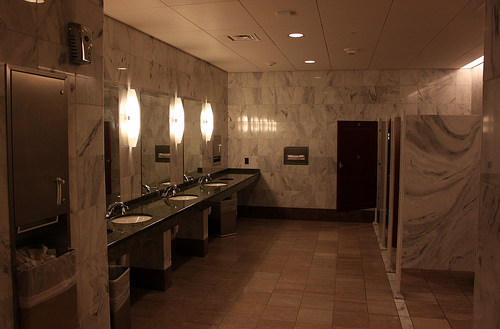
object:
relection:
[229, 108, 285, 138]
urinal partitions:
[367, 107, 480, 295]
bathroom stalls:
[404, 110, 497, 296]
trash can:
[217, 198, 238, 235]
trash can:
[105, 261, 134, 327]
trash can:
[15, 242, 80, 327]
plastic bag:
[212, 199, 235, 237]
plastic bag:
[110, 263, 132, 308]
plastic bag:
[10, 248, 77, 327]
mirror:
[102, 88, 121, 204]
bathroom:
[7, 2, 495, 324]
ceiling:
[126, 1, 481, 65]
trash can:
[4, 236, 97, 327]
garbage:
[3, 229, 80, 266]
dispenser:
[283, 145, 309, 165]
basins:
[109, 214, 157, 223]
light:
[236, 116, 276, 133]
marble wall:
[226, 67, 471, 206]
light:
[199, 101, 213, 141]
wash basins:
[169, 195, 198, 202]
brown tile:
[182, 215, 390, 327]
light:
[124, 88, 140, 147]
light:
[305, 61, 316, 66]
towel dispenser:
[4, 58, 76, 240]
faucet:
[196, 173, 212, 189]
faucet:
[160, 183, 178, 197]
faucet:
[104, 197, 129, 220]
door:
[334, 120, 374, 210]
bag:
[14, 243, 54, 266]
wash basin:
[167, 191, 198, 202]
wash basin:
[204, 180, 228, 189]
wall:
[102, 14, 222, 211]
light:
[285, 33, 306, 38]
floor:
[118, 215, 486, 326]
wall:
[228, 73, 474, 227]